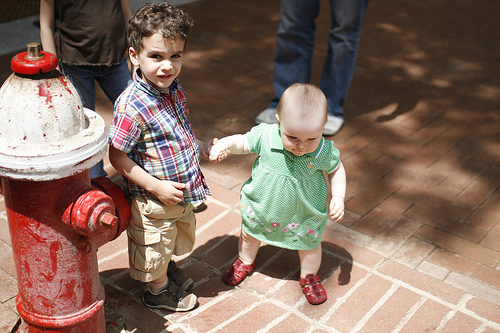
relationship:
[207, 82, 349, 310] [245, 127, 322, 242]
baby in dress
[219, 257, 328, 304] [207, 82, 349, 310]
sandal's are on baby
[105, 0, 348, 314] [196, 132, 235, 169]
two children holding hands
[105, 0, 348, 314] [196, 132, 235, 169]
two children hold hands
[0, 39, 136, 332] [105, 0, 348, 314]
fire hydrant beside two children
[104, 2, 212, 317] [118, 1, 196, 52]
boy has hair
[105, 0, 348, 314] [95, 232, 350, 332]
two children cast shadows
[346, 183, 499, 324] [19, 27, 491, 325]
bricks are on ground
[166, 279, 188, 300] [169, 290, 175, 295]
straps are made from velcro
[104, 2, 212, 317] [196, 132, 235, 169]
boy holding hands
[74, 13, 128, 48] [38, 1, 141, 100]
belly of woman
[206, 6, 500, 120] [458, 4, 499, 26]
shade from tree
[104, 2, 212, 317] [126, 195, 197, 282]
boy in pants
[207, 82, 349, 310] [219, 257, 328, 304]
baby wearing sandal's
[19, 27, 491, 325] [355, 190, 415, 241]
ground has slabs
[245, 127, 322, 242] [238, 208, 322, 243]
dress has flowers